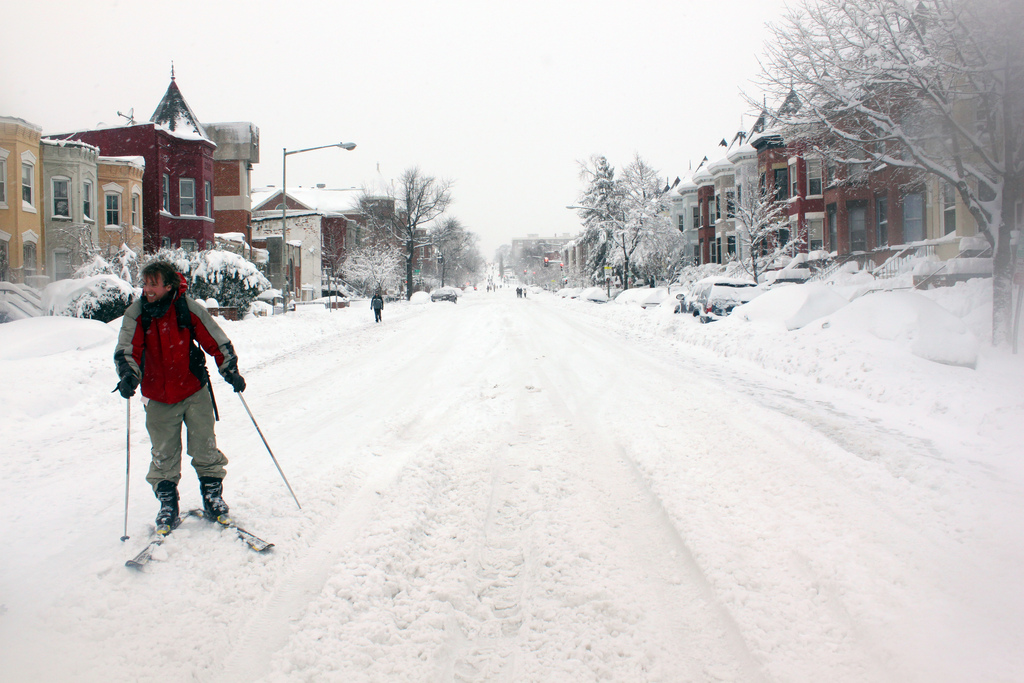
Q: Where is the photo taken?
A: Downtown.